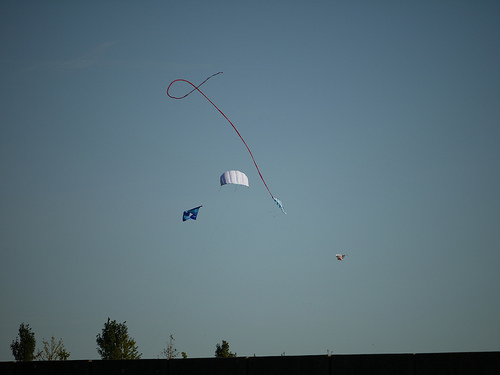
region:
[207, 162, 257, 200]
white para sail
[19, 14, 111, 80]
white clouds in blue sky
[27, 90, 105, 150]
white clouds in blue sky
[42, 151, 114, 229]
white clouds in blue sky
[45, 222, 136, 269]
white clouds in blue sky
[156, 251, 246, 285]
white clouds in blue sky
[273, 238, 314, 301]
white clouds in blue sky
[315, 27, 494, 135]
white clouds in blue sky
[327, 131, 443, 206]
white clouds in blue sky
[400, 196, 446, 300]
white clouds in blue sky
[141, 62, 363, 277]
four kites flying in the air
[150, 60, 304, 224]
kite with long red tail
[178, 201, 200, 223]
blue square shaped kite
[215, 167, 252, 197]
all white kite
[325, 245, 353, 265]
small red and white kite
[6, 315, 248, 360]
trees on the horizon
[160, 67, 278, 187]
long red tail of kite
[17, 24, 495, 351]
sky kites are flying in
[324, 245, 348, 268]
kite flying closest to the ground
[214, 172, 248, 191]
biggest kite flying in the air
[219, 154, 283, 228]
white para sail in sky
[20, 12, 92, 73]
white clouds in light blue sky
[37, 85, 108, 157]
white clouds in light blue sky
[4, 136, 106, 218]
white clouds in light blue sky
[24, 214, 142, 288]
white clouds in light blue sky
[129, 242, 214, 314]
white clouds in light blue sky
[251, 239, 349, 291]
white clouds in light blue sky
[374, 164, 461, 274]
white clouds in light blue sky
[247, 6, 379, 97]
white clouds in light blue sky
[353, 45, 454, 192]
white clouds in light blue sky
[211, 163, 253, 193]
A large white kite.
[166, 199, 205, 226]
A diamond shaped blue kite.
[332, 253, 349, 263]
A small yellow kite.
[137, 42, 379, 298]
Four kites flying in the sky.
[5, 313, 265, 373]
A cluster of leafy trees.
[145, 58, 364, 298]
A group of kites in the sky.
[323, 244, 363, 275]
A small, colorful kite.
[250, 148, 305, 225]
A kite with a long red tail.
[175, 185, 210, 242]
A blue kite with no tail.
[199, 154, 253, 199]
A puffy white kite.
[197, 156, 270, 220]
bllue and white kite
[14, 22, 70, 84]
white clouds in blue sky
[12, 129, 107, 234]
white clouds in blue sky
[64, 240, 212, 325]
white clouds in blue sky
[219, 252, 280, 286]
white clouds in blue sky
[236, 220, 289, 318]
white clouds in blue sky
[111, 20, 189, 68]
white clouds in blue sky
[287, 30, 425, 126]
white clouds in blue sky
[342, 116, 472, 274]
white clouds in blue sky